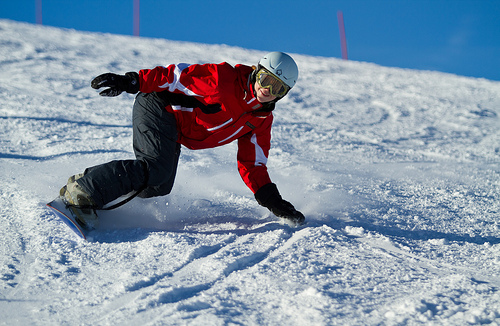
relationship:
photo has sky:
[1, 1, 499, 325] [2, 1, 499, 83]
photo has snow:
[1, 1, 499, 325] [0, 21, 499, 325]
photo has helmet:
[1, 1, 499, 325] [259, 53, 305, 87]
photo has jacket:
[1, 1, 499, 325] [143, 65, 276, 200]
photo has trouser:
[1, 1, 499, 325] [83, 92, 180, 214]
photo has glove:
[1, 1, 499, 325] [92, 67, 139, 100]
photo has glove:
[1, 1, 499, 325] [254, 180, 305, 222]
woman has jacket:
[58, 52, 307, 237] [143, 65, 276, 200]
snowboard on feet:
[47, 191, 88, 242] [63, 172, 104, 230]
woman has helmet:
[58, 52, 307, 237] [259, 53, 305, 87]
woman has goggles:
[58, 52, 307, 237] [254, 72, 289, 97]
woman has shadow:
[58, 52, 307, 237] [310, 211, 499, 251]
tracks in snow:
[121, 228, 299, 306] [0, 21, 499, 325]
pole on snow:
[332, 11, 356, 63] [0, 21, 499, 325]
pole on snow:
[123, 0, 152, 41] [0, 21, 499, 325]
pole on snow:
[30, 2, 47, 31] [0, 21, 499, 325]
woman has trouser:
[58, 52, 307, 237] [83, 92, 180, 214]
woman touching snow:
[58, 52, 307, 237] [0, 21, 499, 325]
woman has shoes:
[58, 52, 307, 237] [64, 173, 99, 226]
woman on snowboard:
[58, 52, 307, 237] [47, 191, 88, 242]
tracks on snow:
[121, 228, 299, 306] [0, 21, 499, 325]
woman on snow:
[58, 52, 307, 237] [0, 21, 499, 325]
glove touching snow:
[254, 180, 305, 222] [0, 21, 499, 325]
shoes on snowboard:
[64, 173, 99, 226] [47, 191, 88, 242]